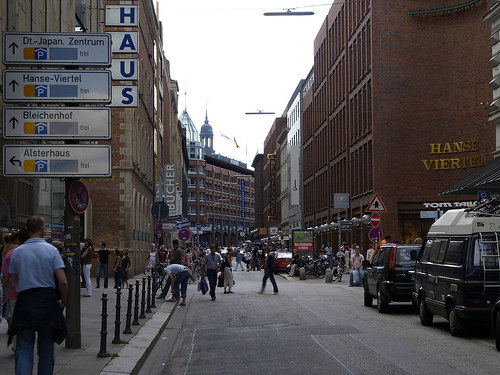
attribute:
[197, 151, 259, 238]
building — gray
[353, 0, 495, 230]
wall — gray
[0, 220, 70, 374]
man — light skinned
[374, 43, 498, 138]
wall — brick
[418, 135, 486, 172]
writing — gray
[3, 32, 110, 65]
direction sign — gray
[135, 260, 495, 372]
street — gray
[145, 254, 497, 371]
road — gray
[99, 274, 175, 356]
poles — short